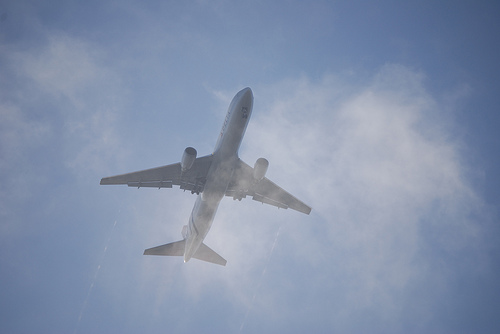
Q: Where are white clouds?
A: In the sky.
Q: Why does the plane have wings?
A: To fly.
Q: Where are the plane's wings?
A: On sides of the plane.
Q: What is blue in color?
A: The sky.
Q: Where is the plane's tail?
A: On back of the plane.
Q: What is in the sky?
A: Jet.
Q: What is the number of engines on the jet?
A: 2.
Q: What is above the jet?
A: Sky.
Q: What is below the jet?
A: Clouds.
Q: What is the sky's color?
A: Blue.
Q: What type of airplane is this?
A: Jet.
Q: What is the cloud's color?
A: White.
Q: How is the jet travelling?
A: Flying.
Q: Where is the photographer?
A: Below the jet.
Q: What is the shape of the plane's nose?
A: Pointed.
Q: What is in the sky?
A: Airplane.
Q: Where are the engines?
A: On the plane.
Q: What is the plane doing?
A: Flying.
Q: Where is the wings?
A: On the plane.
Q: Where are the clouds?
A: In the sky.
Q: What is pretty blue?
A: Sky.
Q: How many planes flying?
A: One.